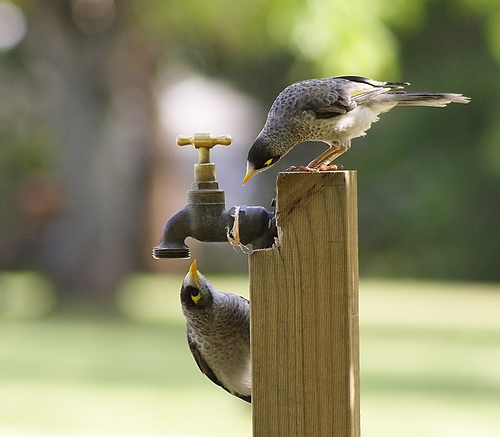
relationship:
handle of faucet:
[175, 127, 240, 182] [155, 121, 272, 261]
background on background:
[0, 0, 500, 318] [10, 69, 498, 185]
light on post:
[346, 360, 356, 414] [248, 170, 360, 437]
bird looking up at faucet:
[180, 259, 250, 405] [138, 123, 281, 274]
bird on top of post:
[243, 76, 472, 186] [243, 161, 362, 435]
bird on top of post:
[180, 259, 250, 405] [243, 161, 362, 435]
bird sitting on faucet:
[243, 76, 472, 186] [151, 133, 277, 260]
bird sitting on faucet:
[180, 259, 250, 405] [151, 133, 277, 260]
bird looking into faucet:
[229, 83, 429, 177] [162, 107, 314, 288]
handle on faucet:
[176, 133, 232, 181] [152, 128, 269, 258]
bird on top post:
[177, 253, 247, 402] [243, 161, 362, 435]